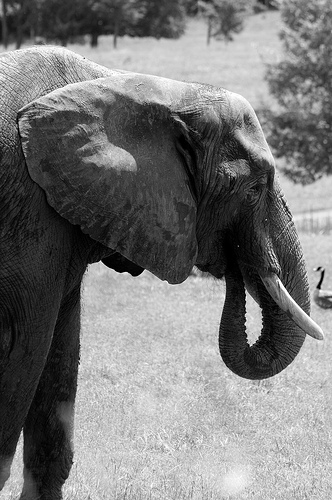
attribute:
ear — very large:
[15, 72, 208, 286]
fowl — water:
[313, 265, 331, 309]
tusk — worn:
[251, 258, 327, 346]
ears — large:
[15, 74, 201, 285]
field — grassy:
[74, 228, 329, 498]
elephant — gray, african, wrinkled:
[0, 45, 321, 499]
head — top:
[183, 93, 281, 288]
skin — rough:
[67, 130, 176, 223]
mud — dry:
[159, 205, 201, 267]